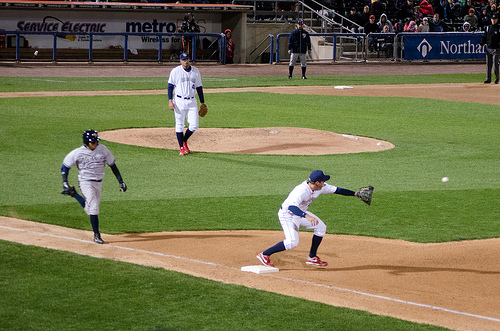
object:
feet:
[179, 147, 186, 155]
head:
[178, 53, 191, 67]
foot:
[256, 252, 276, 269]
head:
[82, 128, 100, 149]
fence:
[274, 31, 499, 65]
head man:
[55, 129, 129, 245]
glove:
[354, 185, 375, 206]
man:
[252, 169, 373, 268]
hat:
[309, 169, 331, 182]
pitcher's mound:
[96, 126, 394, 157]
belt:
[177, 94, 195, 100]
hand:
[303, 214, 320, 226]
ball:
[441, 176, 448, 183]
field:
[0, 62, 500, 331]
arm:
[196, 71, 204, 103]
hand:
[169, 101, 176, 112]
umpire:
[478, 13, 500, 84]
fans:
[380, 25, 390, 34]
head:
[307, 169, 329, 188]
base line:
[0, 223, 500, 321]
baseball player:
[256, 170, 374, 269]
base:
[240, 265, 280, 275]